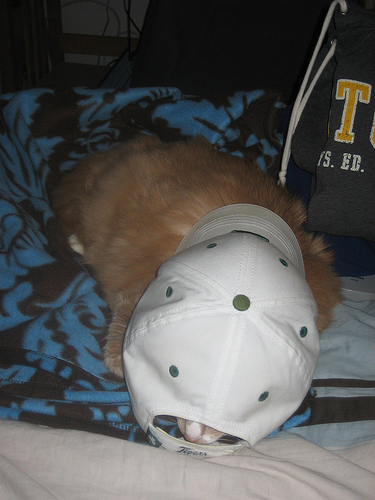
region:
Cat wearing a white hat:
[136, 227, 322, 428]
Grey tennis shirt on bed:
[304, 70, 374, 210]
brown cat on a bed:
[103, 127, 263, 292]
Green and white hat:
[222, 288, 301, 381]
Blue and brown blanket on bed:
[54, 84, 234, 138]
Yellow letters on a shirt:
[324, 67, 374, 145]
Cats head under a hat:
[106, 272, 261, 430]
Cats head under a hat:
[139, 311, 232, 458]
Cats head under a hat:
[182, 360, 226, 455]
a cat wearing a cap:
[51, 118, 343, 466]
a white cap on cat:
[113, 193, 323, 458]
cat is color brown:
[50, 120, 350, 467]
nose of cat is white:
[174, 417, 217, 449]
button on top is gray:
[218, 282, 257, 320]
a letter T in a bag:
[323, 60, 370, 150]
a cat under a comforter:
[1, 70, 316, 445]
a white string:
[273, 0, 337, 180]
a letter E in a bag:
[334, 148, 351, 174]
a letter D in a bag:
[346, 152, 366, 175]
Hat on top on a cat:
[144, 239, 310, 315]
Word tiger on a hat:
[170, 437, 226, 476]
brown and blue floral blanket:
[36, 308, 101, 424]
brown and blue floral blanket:
[74, 74, 224, 120]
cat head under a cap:
[128, 329, 251, 423]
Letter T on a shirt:
[297, 53, 373, 184]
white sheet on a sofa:
[314, 312, 374, 470]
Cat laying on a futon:
[85, 174, 304, 456]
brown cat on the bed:
[97, 162, 208, 320]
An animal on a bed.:
[48, 126, 351, 474]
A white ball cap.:
[119, 197, 331, 461]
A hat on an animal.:
[56, 123, 345, 467]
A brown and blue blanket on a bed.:
[3, 80, 314, 448]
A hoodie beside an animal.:
[268, 4, 370, 247]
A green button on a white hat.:
[221, 286, 256, 319]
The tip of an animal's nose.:
[169, 411, 230, 447]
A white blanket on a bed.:
[3, 420, 363, 493]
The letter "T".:
[330, 75, 371, 148]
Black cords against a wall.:
[87, 1, 153, 94]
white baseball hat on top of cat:
[128, 209, 319, 450]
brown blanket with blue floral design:
[15, 71, 262, 412]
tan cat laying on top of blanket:
[68, 107, 301, 428]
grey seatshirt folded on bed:
[303, 0, 373, 235]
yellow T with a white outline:
[325, 74, 373, 147]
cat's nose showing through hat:
[176, 418, 227, 444]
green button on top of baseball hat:
[220, 287, 259, 324]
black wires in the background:
[102, 0, 151, 85]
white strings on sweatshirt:
[275, 0, 352, 191]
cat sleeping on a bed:
[68, 128, 339, 436]